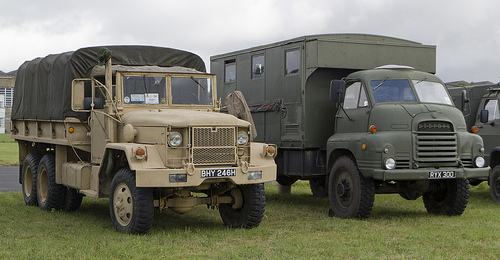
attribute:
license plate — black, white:
[201, 169, 237, 177]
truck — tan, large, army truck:
[10, 44, 277, 233]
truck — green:
[209, 32, 491, 218]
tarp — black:
[11, 44, 207, 118]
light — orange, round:
[136, 147, 145, 160]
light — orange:
[266, 146, 276, 155]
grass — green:
[3, 185, 497, 259]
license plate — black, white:
[429, 170, 455, 178]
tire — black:
[327, 154, 374, 220]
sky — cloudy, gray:
[0, 1, 498, 84]